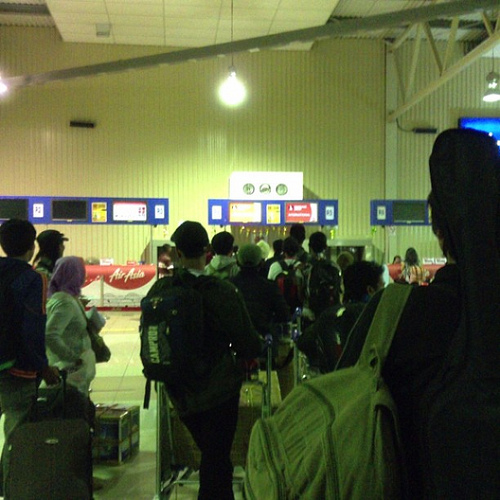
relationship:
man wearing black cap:
[144, 218, 268, 499] [170, 220, 210, 248]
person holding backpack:
[349, 143, 499, 497] [242, 279, 418, 499]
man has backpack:
[139, 218, 267, 499] [134, 270, 229, 374]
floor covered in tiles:
[106, 313, 133, 332] [108, 348, 137, 399]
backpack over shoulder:
[254, 242, 412, 499] [332, 267, 485, 366]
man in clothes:
[139, 218, 267, 499] [139, 260, 260, 498]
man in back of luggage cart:
[139, 218, 267, 499] [162, 320, 303, 498]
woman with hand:
[38, 249, 104, 401] [68, 355, 88, 367]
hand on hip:
[68, 355, 88, 367] [49, 342, 99, 378]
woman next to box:
[38, 249, 104, 401] [84, 394, 149, 469]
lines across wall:
[8, 20, 417, 261] [4, 28, 498, 284]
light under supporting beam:
[209, 68, 258, 109] [2, 0, 496, 109]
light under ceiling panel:
[209, 68, 258, 109] [37, 0, 340, 58]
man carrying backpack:
[139, 218, 267, 499] [135, 270, 220, 400]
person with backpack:
[264, 235, 310, 316] [270, 255, 309, 315]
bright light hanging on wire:
[211, 75, 248, 110] [228, 0, 235, 75]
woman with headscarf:
[38, 249, 104, 401] [46, 256, 86, 299]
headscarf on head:
[46, 256, 86, 299] [49, 250, 94, 299]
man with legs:
[139, 218, 267, 499] [168, 384, 246, 496]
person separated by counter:
[392, 253, 403, 263] [387, 263, 444, 282]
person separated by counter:
[399, 244, 423, 281] [387, 263, 444, 282]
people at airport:
[0, 128, 500, 500] [1, 0, 498, 498]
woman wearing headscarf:
[38, 249, 104, 401] [44, 252, 86, 297]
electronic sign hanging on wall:
[1, 194, 168, 226] [4, 28, 498, 284]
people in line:
[143, 193, 387, 470] [134, 210, 375, 498]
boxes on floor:
[77, 395, 156, 465] [74, 306, 240, 496]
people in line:
[0, 128, 500, 500] [126, 209, 351, 492]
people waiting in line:
[0, 128, 500, 500] [65, 191, 432, 443]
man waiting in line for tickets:
[139, 218, 267, 499] [187, 192, 359, 227]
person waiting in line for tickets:
[224, 242, 292, 334] [187, 192, 359, 227]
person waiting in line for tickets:
[46, 254, 112, 394] [187, 192, 359, 227]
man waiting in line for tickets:
[0, 215, 60, 454] [187, 192, 359, 227]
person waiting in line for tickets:
[293, 257, 387, 373] [187, 192, 359, 227]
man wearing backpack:
[139, 218, 267, 499] [135, 295, 201, 392]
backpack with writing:
[135, 295, 201, 392] [137, 319, 167, 372]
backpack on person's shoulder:
[242, 279, 418, 499] [333, 283, 434, 368]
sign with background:
[203, 198, 339, 227] [208, 201, 342, 225]